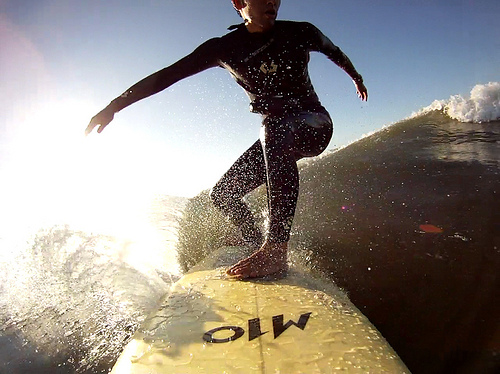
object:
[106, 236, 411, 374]
surfboard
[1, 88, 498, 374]
water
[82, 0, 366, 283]
man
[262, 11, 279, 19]
mouth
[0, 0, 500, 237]
sky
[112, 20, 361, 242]
wet suit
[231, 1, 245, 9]
ear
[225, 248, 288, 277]
foot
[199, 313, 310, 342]
m10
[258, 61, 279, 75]
logo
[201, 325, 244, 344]
letter